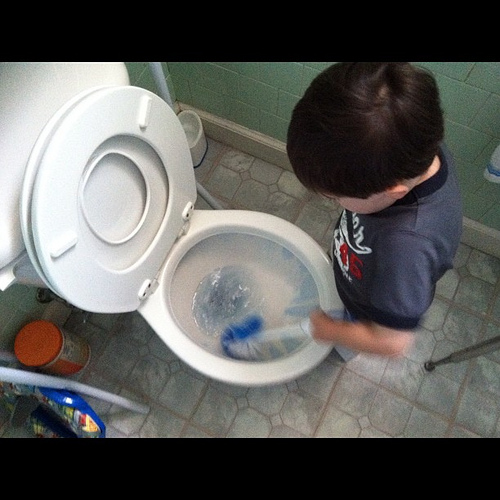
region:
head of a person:
[290, 66, 452, 216]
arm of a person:
[312, 317, 382, 364]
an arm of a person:
[290, 310, 387, 374]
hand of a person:
[297, 301, 328, 358]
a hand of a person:
[298, 303, 343, 363]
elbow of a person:
[389, 351, 427, 365]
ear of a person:
[376, 161, 413, 203]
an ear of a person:
[391, 167, 424, 204]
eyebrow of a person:
[322, 178, 359, 200]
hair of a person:
[335, 94, 418, 145]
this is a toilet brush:
[192, 303, 347, 355]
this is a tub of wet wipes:
[10, 318, 108, 381]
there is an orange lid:
[7, 310, 112, 380]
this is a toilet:
[10, 82, 407, 404]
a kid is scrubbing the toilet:
[202, 55, 474, 446]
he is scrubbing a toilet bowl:
[190, 48, 482, 397]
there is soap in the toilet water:
[192, 268, 269, 342]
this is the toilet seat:
[20, 81, 210, 324]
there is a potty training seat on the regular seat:
[60, 120, 175, 280]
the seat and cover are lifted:
[20, 75, 240, 340]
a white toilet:
[25, 93, 345, 371]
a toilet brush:
[204, 308, 322, 370]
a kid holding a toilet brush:
[214, 143, 435, 375]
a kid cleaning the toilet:
[245, 145, 432, 338]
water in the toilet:
[203, 269, 248, 314]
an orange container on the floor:
[13, 326, 87, 363]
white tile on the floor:
[156, 388, 428, 420]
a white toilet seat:
[17, 113, 227, 306]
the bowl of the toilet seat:
[168, 216, 319, 360]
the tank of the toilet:
[3, 65, 115, 180]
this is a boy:
[256, 40, 477, 425]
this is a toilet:
[9, 76, 410, 436]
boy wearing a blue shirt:
[295, 157, 488, 365]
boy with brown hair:
[268, 44, 490, 225]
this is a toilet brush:
[160, 245, 355, 395]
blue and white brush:
[214, 281, 334, 381]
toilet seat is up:
[36, 80, 260, 330]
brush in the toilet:
[160, 167, 351, 429]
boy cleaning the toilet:
[35, 54, 493, 461]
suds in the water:
[183, 262, 282, 356]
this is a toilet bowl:
[163, 218, 360, 395]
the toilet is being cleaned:
[2, 64, 359, 409]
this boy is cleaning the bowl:
[275, 45, 477, 441]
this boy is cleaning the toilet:
[262, 48, 484, 428]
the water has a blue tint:
[185, 258, 279, 343]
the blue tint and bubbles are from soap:
[176, 258, 285, 351]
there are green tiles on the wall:
[196, 63, 281, 115]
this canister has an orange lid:
[3, 305, 103, 379]